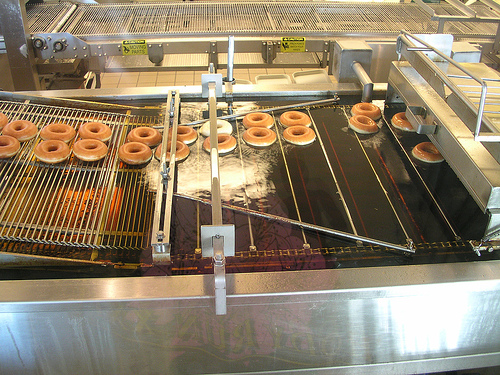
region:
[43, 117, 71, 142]
donut on a rack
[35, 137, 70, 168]
donut on a rack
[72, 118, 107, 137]
donut on a rack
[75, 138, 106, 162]
donut on a rack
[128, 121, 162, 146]
donut on a rack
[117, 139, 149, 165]
donut on a rack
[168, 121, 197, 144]
donut on a rack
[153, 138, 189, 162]
donut on a rack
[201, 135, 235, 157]
donut on a rack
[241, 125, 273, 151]
donut on a rack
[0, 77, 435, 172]
THE DOUGHNUTS ARE ON THE CONVEYOR BELT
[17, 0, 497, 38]
THIS CONVEYOR BELT IS EMPTY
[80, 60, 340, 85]
THE FLOOR IS TILE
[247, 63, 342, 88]
THE TRAYS ARE WHITE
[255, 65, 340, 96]
THE TRAYS ARE ON THE FLOOR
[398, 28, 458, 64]
THE TOWEL IS WHITE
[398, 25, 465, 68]
THE TOWEL IS HANGING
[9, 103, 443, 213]
Dougnuts on a rck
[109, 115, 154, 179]
two doughnuts on a rack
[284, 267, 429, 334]
the edge of a silver fryer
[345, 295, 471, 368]
a reflection of a light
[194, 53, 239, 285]
a steel bar across the machine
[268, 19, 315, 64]
a yellow and black sign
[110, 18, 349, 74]
two yellow and black signs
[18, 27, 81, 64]
two knobs on a machine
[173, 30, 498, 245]
donuts coming out of the ovens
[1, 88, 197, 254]
donuts on a conveyor belt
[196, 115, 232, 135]
single white donut on the line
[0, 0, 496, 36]
another conveyor belt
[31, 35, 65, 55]
knobs on the side of the belt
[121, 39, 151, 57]
yellow and black caution sign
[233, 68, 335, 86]
metal trays between the conveyors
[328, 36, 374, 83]
controls for conveyor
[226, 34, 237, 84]
poles holing up tables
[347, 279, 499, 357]
light reflecting off the table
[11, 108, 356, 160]
many donuts on a rack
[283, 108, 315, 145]
two glazed donuts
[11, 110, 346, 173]
many glazed donuts at a bakery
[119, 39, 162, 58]
small yellow warning sign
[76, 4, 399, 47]
empty metal racks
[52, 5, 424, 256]
lots of metal baking equipment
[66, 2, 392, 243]
industrial metal cooking equipment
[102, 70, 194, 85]
floor under the metal equipment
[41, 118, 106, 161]
four glazed donuts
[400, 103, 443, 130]
handle on a piece of equipment